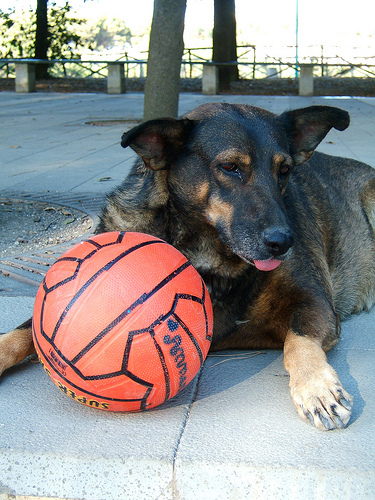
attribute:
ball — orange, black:
[27, 230, 214, 414]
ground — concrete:
[7, 89, 374, 488]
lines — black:
[30, 234, 214, 408]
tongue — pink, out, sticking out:
[251, 253, 288, 274]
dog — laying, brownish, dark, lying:
[278, 336, 362, 428]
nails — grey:
[302, 390, 353, 429]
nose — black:
[259, 221, 297, 252]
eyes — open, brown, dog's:
[218, 144, 295, 188]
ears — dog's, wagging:
[117, 94, 354, 181]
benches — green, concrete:
[6, 57, 374, 97]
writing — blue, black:
[165, 318, 190, 398]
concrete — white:
[3, 93, 374, 488]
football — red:
[25, 230, 223, 409]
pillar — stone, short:
[13, 62, 45, 92]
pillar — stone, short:
[104, 62, 129, 96]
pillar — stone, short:
[199, 64, 220, 93]